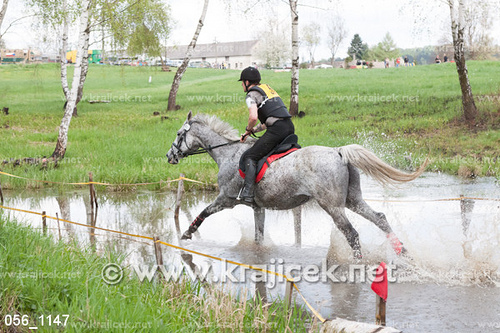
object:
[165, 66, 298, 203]
jockey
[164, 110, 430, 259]
horse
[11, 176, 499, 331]
water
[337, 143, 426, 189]
tail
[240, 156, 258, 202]
boots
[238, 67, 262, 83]
hat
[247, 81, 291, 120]
vest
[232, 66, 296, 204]
man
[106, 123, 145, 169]
grass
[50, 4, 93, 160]
tree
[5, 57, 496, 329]
barracks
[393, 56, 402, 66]
people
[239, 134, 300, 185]
saddle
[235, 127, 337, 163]
back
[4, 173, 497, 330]
swamp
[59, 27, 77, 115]
stem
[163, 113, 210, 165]
head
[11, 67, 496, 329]
plantation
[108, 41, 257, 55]
roof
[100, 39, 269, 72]
house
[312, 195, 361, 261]
leg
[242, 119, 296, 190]
pants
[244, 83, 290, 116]
shirt